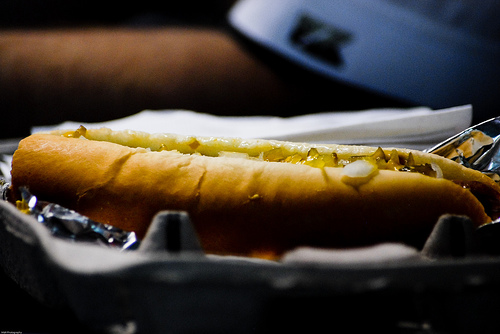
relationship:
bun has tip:
[4, 120, 500, 263] [472, 164, 499, 223]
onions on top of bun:
[346, 168, 378, 187] [71, 154, 178, 208]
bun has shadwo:
[71, 154, 178, 208] [250, 212, 314, 239]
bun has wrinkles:
[71, 154, 178, 208] [194, 176, 209, 193]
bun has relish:
[4, 120, 500, 263] [393, 155, 442, 187]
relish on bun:
[393, 155, 442, 187] [4, 120, 500, 263]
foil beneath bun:
[54, 209, 109, 241] [4, 120, 500, 263]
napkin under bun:
[29, 102, 474, 152] [4, 120, 500, 263]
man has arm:
[4, 1, 491, 107] [12, 21, 274, 105]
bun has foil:
[4, 120, 500, 263] [32, 202, 140, 251]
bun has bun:
[4, 120, 500, 263] [71, 154, 178, 208]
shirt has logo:
[223, 0, 499, 110] [291, 12, 361, 73]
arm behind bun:
[12, 21, 274, 105] [4, 120, 500, 263]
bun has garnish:
[4, 120, 500, 263] [290, 140, 415, 186]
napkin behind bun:
[318, 115, 416, 141] [4, 120, 500, 263]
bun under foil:
[4, 120, 500, 263] [32, 202, 140, 251]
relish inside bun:
[393, 155, 442, 187] [71, 154, 178, 208]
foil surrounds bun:
[54, 209, 109, 241] [4, 120, 500, 263]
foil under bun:
[54, 209, 109, 241] [4, 120, 500, 263]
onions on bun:
[346, 168, 378, 187] [71, 154, 178, 208]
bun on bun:
[4, 120, 500, 263] [9, 120, 494, 253]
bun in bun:
[4, 120, 500, 263] [9, 120, 494, 253]